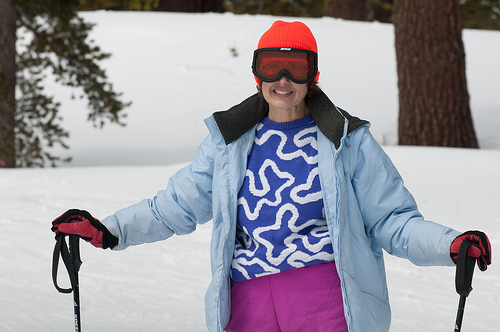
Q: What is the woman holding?
A: Ski poles.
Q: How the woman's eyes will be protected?
A: With goggles.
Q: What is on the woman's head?
A: A hat.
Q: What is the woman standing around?
A: Snow.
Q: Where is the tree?
A: Behind the woman.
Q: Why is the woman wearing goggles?
A: Protection.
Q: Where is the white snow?
A: On the ground.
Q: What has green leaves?
A: Brown tree.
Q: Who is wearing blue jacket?
A: The woman.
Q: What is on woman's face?
A: Snow goggles.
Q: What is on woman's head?
A: Red hat.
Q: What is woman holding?
A: Ski poles.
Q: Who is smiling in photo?
A: The woman.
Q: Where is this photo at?
A: Snow slopes.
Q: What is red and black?
A: Gloves.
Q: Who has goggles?
A: The woman.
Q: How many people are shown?
A: One.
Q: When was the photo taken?
A: Winter.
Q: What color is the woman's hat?
A: Red.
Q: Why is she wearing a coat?
A: It is cold.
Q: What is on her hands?
A: Gloves.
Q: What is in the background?
A: Trees.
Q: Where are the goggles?
A: On her face.